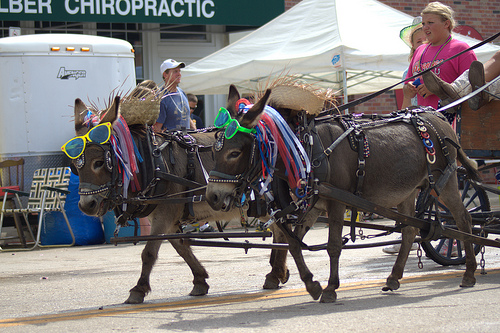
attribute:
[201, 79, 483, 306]
donkey — green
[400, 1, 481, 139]
woman — pink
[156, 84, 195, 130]
shirt — blue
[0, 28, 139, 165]
trailer — white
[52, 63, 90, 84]
logo — black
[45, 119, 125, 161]
sunglasses — yellow